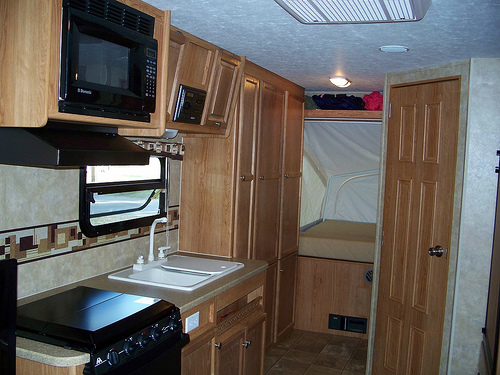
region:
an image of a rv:
[6, 2, 497, 372]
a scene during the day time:
[7, 12, 497, 369]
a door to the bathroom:
[359, 46, 489, 373]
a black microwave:
[43, 0, 188, 132]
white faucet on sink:
[147, 214, 168, 254]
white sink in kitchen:
[127, 250, 210, 301]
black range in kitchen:
[25, 271, 173, 366]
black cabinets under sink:
[215, 293, 261, 373]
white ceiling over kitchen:
[192, 12, 340, 84]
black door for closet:
[372, 101, 451, 367]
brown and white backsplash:
[17, 189, 83, 291]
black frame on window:
[86, 152, 189, 232]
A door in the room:
[393, 137, 443, 264]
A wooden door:
[385, 144, 446, 309]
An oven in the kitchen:
[66, 281, 170, 363]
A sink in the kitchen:
[134, 230, 255, 308]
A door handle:
[412, 240, 452, 262]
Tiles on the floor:
[297, 336, 357, 373]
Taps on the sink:
[144, 214, 179, 271]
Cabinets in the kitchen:
[237, 139, 297, 222]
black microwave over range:
[61, 4, 161, 138]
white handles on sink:
[132, 244, 177, 276]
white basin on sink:
[108, 241, 239, 290]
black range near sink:
[65, 270, 149, 348]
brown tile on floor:
[275, 346, 346, 367]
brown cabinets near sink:
[226, 86, 318, 266]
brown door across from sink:
[360, 93, 465, 338]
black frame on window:
[79, 159, 184, 241]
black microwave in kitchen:
[58, 16, 155, 128]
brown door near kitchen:
[393, 89, 443, 371]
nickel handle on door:
[429, 237, 450, 262]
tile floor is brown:
[282, 319, 336, 367]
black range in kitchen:
[60, 250, 155, 371]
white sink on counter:
[122, 249, 226, 307]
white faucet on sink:
[125, 209, 182, 266]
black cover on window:
[75, 152, 180, 235]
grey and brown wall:
[13, 184, 70, 275]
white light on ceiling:
[315, 56, 359, 100]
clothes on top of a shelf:
[302, 83, 381, 111]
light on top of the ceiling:
[323, 66, 353, 96]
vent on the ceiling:
[267, 0, 434, 22]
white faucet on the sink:
[126, 197, 182, 269]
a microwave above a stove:
[6, 0, 186, 372]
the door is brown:
[364, 72, 471, 374]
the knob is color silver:
[424, 239, 446, 260]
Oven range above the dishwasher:
[0, 119, 152, 169]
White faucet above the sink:
[130, 214, 172, 266]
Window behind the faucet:
[76, 157, 169, 239]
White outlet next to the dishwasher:
[182, 308, 200, 333]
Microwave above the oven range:
[56, 0, 157, 124]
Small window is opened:
[75, 154, 169, 239]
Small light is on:
[325, 73, 352, 88]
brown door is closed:
[371, 75, 461, 373]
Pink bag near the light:
[362, 90, 384, 112]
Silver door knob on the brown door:
[425, 241, 442, 258]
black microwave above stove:
[57, 0, 158, 122]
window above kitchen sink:
[91, 189, 159, 224]